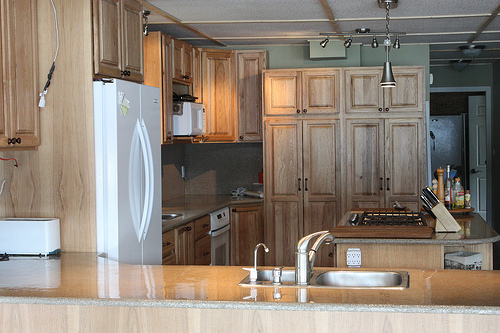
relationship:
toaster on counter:
[2, 214, 66, 264] [2, 247, 498, 314]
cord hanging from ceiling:
[25, 29, 82, 115] [211, 5, 309, 55]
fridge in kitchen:
[91, 76, 164, 266] [3, 0, 490, 332]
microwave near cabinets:
[166, 93, 211, 143] [198, 49, 440, 244]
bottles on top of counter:
[434, 160, 477, 223] [327, 207, 499, 244]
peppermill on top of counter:
[435, 162, 445, 198] [327, 207, 499, 244]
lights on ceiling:
[318, 30, 405, 47] [133, 1, 498, 65]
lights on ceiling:
[377, 2, 396, 87] [133, 1, 498, 65]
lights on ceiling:
[140, 8, 148, 34] [133, 1, 498, 65]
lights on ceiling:
[457, 42, 483, 54] [133, 1, 498, 65]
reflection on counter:
[132, 274, 211, 304] [2, 237, 498, 312]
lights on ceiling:
[318, 30, 405, 49] [142, 2, 499, 70]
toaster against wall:
[0, 217, 62, 257] [0, 0, 94, 250]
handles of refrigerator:
[138, 116, 158, 240] [87, 66, 175, 271]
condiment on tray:
[454, 173, 474, 204] [435, 200, 477, 212]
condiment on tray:
[442, 172, 454, 204] [435, 200, 477, 212]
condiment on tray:
[434, 165, 447, 202] [435, 200, 477, 212]